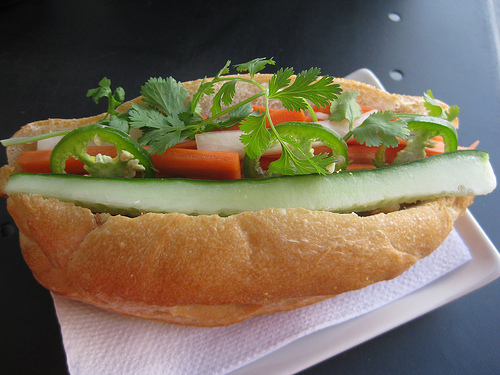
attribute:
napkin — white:
[50, 208, 499, 375]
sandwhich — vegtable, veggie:
[0, 56, 499, 328]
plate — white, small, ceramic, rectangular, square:
[229, 206, 499, 373]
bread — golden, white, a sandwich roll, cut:
[7, 72, 475, 325]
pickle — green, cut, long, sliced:
[3, 151, 498, 212]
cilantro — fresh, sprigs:
[0, 56, 460, 174]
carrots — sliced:
[18, 103, 480, 178]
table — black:
[0, 0, 498, 374]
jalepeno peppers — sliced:
[48, 121, 459, 177]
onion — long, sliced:
[195, 109, 378, 159]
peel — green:
[7, 148, 488, 184]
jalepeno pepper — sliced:
[48, 124, 155, 180]